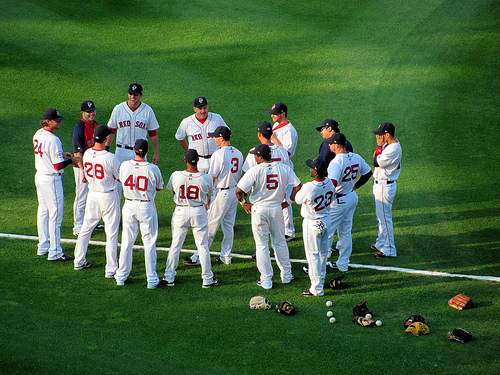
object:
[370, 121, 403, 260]
players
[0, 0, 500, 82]
field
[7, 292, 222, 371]
grass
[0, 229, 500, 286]
chalk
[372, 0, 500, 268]
mow lines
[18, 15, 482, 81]
grass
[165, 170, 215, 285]
uniforms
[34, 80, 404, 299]
group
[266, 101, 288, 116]
hat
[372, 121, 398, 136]
hat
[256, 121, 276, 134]
hat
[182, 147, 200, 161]
hat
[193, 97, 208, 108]
hat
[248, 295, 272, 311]
baseball mitts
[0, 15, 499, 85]
ground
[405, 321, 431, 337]
gloves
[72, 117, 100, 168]
jacket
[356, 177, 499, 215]
shadows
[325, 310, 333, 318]
baseballs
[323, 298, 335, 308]
baseballs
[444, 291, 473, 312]
glove